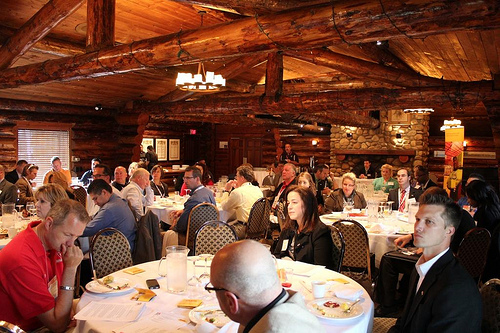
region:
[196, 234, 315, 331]
a bald headed man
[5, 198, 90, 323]
a mean wearing a red shirt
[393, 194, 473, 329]
a mean wearing a black coat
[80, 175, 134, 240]
a mean wearing a blue shirt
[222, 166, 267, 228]
a mean wearing a yellow shirt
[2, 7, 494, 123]
wood beam rafters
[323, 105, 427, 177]
a large stone fireplace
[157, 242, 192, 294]
a clear pitcher of water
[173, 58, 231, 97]
a hanging chandelier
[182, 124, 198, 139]
an exit sign in distance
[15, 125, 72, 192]
a blind covered window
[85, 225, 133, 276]
a brown chair back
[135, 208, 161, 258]
a grey coat on a seat back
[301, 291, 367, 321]
an elated plate of food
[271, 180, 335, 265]
a woman wearing a name badge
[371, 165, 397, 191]
a woman wearing a green blouse and name badge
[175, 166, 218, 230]
a seated man wearing eyeglasses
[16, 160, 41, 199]
a woman wearing a white headband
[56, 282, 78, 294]
a silver wrist watch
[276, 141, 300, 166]
a man standing in back of room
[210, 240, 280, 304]
Man's head is bald on top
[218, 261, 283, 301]
Man has thin hair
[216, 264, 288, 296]
Man's hair is gray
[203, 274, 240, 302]
Man wearing corrective lenses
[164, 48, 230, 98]
Light fixture hanging from ceiling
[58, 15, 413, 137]
Ceiling is open beam style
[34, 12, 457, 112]
Ceiling beams are brown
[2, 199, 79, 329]
Man wearing red shirt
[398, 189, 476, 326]
Man wearing black jacket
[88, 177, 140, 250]
Man wearing blue shirt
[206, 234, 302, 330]
man with bald head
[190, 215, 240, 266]
empty chair at round table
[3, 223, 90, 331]
man with red shirt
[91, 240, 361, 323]
round table with white table cloth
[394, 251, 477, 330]
man with black jacket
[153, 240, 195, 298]
pitcher of ice water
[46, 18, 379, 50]
wood log beams support ceiling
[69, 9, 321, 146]
roof made of wood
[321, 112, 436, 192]
stone fireplace with wood mantle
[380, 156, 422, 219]
man wearing red tie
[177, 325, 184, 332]
THE TABLE CLOTH IS WHITE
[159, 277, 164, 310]
THE TABLE CLOTH IS WHITE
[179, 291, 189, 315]
THE TABLE CLOTH IS WHITE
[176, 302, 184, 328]
THE TABLE CLOTH IS WHITE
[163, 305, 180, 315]
THE TABLE CLOTH IS WHITE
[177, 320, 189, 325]
THE TABLE CLOTH IS WHITE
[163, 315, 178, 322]
THE TABLE CLOTH IS WHITE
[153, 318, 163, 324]
THE TABLE CLOTH IS WHITE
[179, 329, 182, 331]
THE TABLE CLOTH IS WHITE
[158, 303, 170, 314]
THE TABLE CLOTH IS WHITE